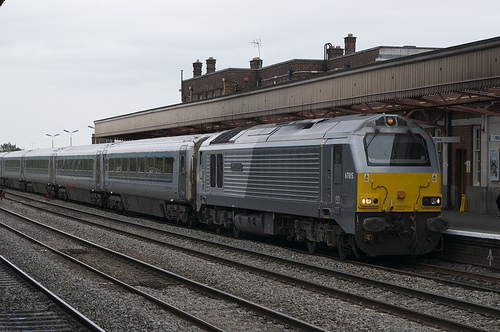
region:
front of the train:
[293, 93, 467, 280]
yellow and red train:
[307, 108, 472, 251]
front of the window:
[348, 112, 442, 183]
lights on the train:
[336, 186, 452, 237]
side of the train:
[172, 119, 359, 226]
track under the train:
[421, 257, 477, 307]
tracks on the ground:
[8, 237, 283, 330]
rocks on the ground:
[231, 281, 286, 311]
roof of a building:
[176, 22, 383, 104]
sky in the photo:
[43, 44, 138, 91]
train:
[5, 120, 440, 222]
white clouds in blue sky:
[18, 10, 34, 31]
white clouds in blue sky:
[42, 60, 64, 82]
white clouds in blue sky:
[112, 47, 176, 77]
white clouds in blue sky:
[27, 23, 77, 85]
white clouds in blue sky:
[34, 83, 64, 113]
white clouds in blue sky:
[77, 49, 112, 84]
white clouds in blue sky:
[119, 19, 165, 64]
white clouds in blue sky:
[228, 9, 260, 40]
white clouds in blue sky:
[372, 13, 410, 36]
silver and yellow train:
[15, 127, 421, 226]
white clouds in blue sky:
[31, 28, 61, 50]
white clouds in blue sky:
[57, 67, 87, 88]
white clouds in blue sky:
[22, 2, 82, 37]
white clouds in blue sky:
[252, 11, 298, 43]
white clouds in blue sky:
[149, 13, 195, 30]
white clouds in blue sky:
[5, 69, 47, 92]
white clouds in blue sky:
[60, 39, 103, 61]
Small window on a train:
[357, 136, 442, 168]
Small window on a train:
[331, 141, 357, 181]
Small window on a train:
[205, 145, 231, 194]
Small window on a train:
[160, 153, 168, 175]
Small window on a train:
[106, 153, 115, 176]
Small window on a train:
[110, 152, 152, 169]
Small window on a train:
[51, 158, 97, 173]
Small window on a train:
[22, 156, 47, 171]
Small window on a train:
[1, 156, 16, 170]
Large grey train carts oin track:
[0, 137, 188, 227]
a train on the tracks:
[14, 134, 485, 249]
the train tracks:
[8, 208, 253, 325]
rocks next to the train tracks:
[191, 259, 250, 294]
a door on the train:
[322, 154, 342, 197]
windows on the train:
[103, 158, 176, 181]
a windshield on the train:
[364, 136, 428, 162]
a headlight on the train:
[357, 197, 376, 204]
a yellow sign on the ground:
[456, 190, 468, 210]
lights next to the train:
[41, 124, 88, 139]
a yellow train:
[352, 125, 448, 241]